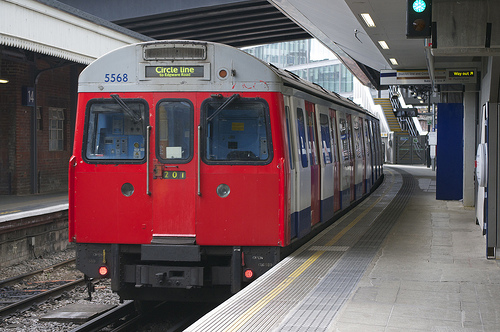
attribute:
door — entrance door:
[140, 91, 218, 252]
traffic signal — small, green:
[394, 7, 471, 45]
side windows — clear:
[291, 95, 351, 166]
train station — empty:
[0, 160, 497, 323]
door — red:
[148, 90, 197, 236]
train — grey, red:
[62, 40, 383, 301]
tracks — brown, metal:
[0, 257, 135, 329]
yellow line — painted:
[222, 192, 382, 329]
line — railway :
[3, 221, 153, 330]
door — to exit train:
[149, 94, 199, 243]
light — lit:
[403, 0, 448, 42]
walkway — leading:
[180, 162, 495, 328]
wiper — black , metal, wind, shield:
[194, 90, 243, 132]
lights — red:
[213, 65, 229, 84]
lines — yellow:
[265, 282, 288, 297]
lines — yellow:
[222, 250, 326, 330]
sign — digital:
[451, 68, 478, 80]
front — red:
[59, 33, 296, 277]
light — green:
[406, 0, 432, 37]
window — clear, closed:
[144, 101, 190, 160]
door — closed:
[145, 100, 192, 239]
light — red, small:
[83, 250, 122, 287]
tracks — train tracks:
[8, 202, 298, 330]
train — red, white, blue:
[82, 53, 384, 208]